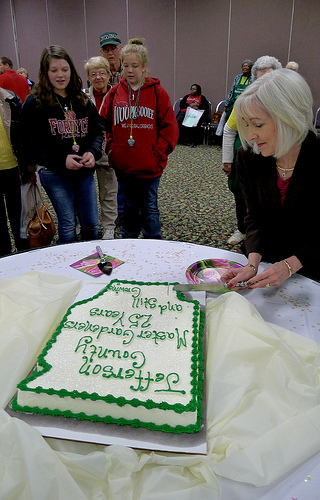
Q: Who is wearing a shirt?
A: The girl is wearing a shirt.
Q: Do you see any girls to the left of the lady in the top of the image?
A: Yes, there is a girl to the left of the lady.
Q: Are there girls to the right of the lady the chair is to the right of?
A: No, the girl is to the left of the lady.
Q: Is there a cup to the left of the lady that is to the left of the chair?
A: No, there is a girl to the left of the lady.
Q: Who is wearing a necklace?
A: The girl is wearing a necklace.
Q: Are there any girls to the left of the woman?
A: Yes, there is a girl to the left of the woman.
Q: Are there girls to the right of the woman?
A: No, the girl is to the left of the woman.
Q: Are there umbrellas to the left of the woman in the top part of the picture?
A: No, there is a girl to the left of the woman.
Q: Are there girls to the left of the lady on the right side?
A: Yes, there is a girl to the left of the lady.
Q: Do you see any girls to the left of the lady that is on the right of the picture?
A: Yes, there is a girl to the left of the lady.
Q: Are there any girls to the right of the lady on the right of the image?
A: No, the girl is to the left of the lady.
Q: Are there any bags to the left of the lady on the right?
A: No, there is a girl to the left of the lady.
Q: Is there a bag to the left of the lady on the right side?
A: No, there is a girl to the left of the lady.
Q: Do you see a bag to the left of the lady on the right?
A: No, there is a girl to the left of the lady.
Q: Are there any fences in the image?
A: No, there are no fences.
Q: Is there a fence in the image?
A: No, there are no fences.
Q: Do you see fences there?
A: No, there are no fences.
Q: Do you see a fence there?
A: No, there are no fences.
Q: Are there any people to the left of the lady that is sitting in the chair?
A: Yes, there is a person to the left of the lady.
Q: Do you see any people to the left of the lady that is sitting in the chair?
A: Yes, there is a person to the left of the lady.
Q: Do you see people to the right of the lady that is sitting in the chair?
A: No, the person is to the left of the lady.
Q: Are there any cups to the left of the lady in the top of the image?
A: No, there is a person to the left of the lady.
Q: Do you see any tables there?
A: Yes, there is a table.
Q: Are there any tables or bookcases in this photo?
A: Yes, there is a table.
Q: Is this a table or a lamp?
A: This is a table.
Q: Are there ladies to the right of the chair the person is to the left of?
A: Yes, there is a lady to the right of the chair.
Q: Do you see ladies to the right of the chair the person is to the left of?
A: Yes, there is a lady to the right of the chair.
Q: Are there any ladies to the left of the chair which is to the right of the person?
A: No, the lady is to the right of the chair.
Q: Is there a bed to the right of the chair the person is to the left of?
A: No, there is a lady to the right of the chair.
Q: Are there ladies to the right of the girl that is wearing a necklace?
A: Yes, there is a lady to the right of the girl.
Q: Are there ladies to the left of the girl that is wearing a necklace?
A: No, the lady is to the right of the girl.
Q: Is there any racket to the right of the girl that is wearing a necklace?
A: No, there is a lady to the right of the girl.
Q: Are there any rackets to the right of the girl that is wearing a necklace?
A: No, there is a lady to the right of the girl.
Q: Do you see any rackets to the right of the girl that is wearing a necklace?
A: No, there is a lady to the right of the girl.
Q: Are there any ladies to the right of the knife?
A: Yes, there is a lady to the right of the knife.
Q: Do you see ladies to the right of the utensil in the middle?
A: Yes, there is a lady to the right of the knife.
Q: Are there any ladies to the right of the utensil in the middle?
A: Yes, there is a lady to the right of the knife.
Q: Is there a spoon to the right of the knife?
A: No, there is a lady to the right of the knife.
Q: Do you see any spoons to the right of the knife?
A: No, there is a lady to the right of the knife.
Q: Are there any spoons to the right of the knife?
A: No, there is a lady to the right of the knife.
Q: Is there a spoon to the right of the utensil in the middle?
A: No, there is a lady to the right of the knife.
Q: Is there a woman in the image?
A: Yes, there is a woman.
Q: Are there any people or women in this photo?
A: Yes, there is a woman.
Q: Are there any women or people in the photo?
A: Yes, there is a woman.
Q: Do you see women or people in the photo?
A: Yes, there is a woman.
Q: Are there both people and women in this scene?
A: Yes, there are both a woman and a person.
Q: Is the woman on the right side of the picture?
A: Yes, the woman is on the right of the image.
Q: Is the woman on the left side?
A: No, the woman is on the right of the image.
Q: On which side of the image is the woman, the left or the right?
A: The woman is on the right of the image.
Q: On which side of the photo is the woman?
A: The woman is on the right of the image.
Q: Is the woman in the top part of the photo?
A: Yes, the woman is in the top of the image.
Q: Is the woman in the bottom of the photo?
A: No, the woman is in the top of the image.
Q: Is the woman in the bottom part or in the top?
A: The woman is in the top of the image.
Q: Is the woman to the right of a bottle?
A: No, the woman is to the right of a chair.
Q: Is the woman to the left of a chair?
A: No, the woman is to the right of a chair.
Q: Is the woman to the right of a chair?
A: Yes, the woman is to the right of a chair.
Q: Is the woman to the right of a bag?
A: No, the woman is to the right of a chair.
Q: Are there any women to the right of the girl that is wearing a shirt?
A: Yes, there is a woman to the right of the girl.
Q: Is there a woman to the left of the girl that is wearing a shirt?
A: No, the woman is to the right of the girl.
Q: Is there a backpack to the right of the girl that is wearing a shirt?
A: No, there is a woman to the right of the girl.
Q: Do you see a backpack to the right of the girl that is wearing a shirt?
A: No, there is a woman to the right of the girl.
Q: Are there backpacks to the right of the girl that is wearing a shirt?
A: No, there is a woman to the right of the girl.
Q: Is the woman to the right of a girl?
A: Yes, the woman is to the right of a girl.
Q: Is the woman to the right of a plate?
A: No, the woman is to the right of a girl.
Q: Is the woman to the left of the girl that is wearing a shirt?
A: No, the woman is to the right of the girl.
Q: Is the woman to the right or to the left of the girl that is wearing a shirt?
A: The woman is to the right of the girl.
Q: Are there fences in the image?
A: No, there are no fences.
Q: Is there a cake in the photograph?
A: Yes, there is a cake.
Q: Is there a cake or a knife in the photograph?
A: Yes, there is a cake.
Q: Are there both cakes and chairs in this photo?
A: Yes, there are both a cake and a chair.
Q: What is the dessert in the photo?
A: The dessert is a cake.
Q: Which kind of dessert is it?
A: The dessert is a cake.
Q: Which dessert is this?
A: That is a cake.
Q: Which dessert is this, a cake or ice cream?
A: That is a cake.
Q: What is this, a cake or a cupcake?
A: This is a cake.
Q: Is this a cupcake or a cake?
A: This is a cake.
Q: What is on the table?
A: The cake is on the table.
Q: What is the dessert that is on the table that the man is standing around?
A: The dessert is a cake.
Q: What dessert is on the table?
A: The dessert is a cake.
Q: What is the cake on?
A: The cake is on the table.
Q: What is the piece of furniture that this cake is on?
A: The piece of furniture is a table.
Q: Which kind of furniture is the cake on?
A: The cake is on the table.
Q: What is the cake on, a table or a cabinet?
A: The cake is on a table.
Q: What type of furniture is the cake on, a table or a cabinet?
A: The cake is on a table.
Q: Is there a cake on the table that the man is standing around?
A: Yes, there is a cake on the table.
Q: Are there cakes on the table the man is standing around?
A: Yes, there is a cake on the table.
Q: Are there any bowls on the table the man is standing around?
A: No, there is a cake on the table.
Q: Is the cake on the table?
A: Yes, the cake is on the table.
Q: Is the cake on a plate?
A: No, the cake is on the table.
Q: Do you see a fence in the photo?
A: No, there are no fences.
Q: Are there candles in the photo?
A: No, there are no candles.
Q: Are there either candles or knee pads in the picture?
A: No, there are no candles or knee pads.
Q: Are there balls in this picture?
A: No, there are no balls.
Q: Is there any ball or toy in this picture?
A: No, there are no balls or toys.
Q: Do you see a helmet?
A: No, there are no helmets.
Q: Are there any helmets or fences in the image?
A: No, there are no helmets or fences.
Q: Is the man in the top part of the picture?
A: Yes, the man is in the top of the image.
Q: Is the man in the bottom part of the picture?
A: No, the man is in the top of the image.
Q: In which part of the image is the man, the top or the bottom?
A: The man is in the top of the image.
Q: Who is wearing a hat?
A: The man is wearing a hat.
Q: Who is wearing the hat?
A: The man is wearing a hat.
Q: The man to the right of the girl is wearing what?
A: The man is wearing a hat.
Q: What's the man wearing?
A: The man is wearing a hat.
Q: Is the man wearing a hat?
A: Yes, the man is wearing a hat.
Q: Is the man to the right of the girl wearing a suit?
A: No, the man is wearing a hat.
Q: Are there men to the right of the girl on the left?
A: Yes, there is a man to the right of the girl.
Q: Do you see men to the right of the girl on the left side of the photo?
A: Yes, there is a man to the right of the girl.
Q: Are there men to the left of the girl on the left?
A: No, the man is to the right of the girl.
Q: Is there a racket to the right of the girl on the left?
A: No, there is a man to the right of the girl.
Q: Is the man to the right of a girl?
A: Yes, the man is to the right of a girl.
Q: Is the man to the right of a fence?
A: No, the man is to the right of a girl.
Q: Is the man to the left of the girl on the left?
A: No, the man is to the right of the girl.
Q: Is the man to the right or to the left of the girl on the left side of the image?
A: The man is to the right of the girl.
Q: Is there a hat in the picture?
A: Yes, there is a hat.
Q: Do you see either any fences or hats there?
A: Yes, there is a hat.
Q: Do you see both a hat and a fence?
A: No, there is a hat but no fences.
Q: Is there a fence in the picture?
A: No, there are no fences.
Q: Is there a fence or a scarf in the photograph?
A: No, there are no fences or scarves.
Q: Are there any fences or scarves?
A: No, there are no fences or scarves.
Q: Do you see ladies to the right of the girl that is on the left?
A: Yes, there is a lady to the right of the girl.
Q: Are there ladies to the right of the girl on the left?
A: Yes, there is a lady to the right of the girl.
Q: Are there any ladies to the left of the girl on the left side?
A: No, the lady is to the right of the girl.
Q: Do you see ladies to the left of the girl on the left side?
A: No, the lady is to the right of the girl.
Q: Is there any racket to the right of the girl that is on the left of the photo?
A: No, there is a lady to the right of the girl.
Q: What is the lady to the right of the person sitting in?
A: The lady is sitting in the chair.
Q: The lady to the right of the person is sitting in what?
A: The lady is sitting in the chair.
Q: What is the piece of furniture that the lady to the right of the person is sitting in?
A: The piece of furniture is a chair.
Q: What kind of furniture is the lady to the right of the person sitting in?
A: The lady is sitting in the chair.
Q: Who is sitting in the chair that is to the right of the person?
A: The lady is sitting in the chair.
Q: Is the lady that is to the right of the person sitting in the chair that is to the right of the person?
A: Yes, the lady is sitting in the chair.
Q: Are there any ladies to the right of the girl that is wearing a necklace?
A: Yes, there is a lady to the right of the girl.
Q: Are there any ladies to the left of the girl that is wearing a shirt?
A: No, the lady is to the right of the girl.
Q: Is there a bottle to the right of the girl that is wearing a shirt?
A: No, there is a lady to the right of the girl.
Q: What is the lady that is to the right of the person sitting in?
A: The lady is sitting in the chair.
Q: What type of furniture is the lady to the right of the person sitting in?
A: The lady is sitting in the chair.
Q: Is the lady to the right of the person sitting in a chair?
A: Yes, the lady is sitting in a chair.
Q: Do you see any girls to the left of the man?
A: Yes, there is a girl to the left of the man.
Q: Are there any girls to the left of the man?
A: Yes, there is a girl to the left of the man.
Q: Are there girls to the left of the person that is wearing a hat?
A: Yes, there is a girl to the left of the man.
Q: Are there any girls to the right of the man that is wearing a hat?
A: No, the girl is to the left of the man.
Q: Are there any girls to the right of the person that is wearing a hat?
A: No, the girl is to the left of the man.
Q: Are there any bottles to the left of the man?
A: No, there is a girl to the left of the man.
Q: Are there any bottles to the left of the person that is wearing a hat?
A: No, there is a girl to the left of the man.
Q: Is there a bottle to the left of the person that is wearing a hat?
A: No, there is a girl to the left of the man.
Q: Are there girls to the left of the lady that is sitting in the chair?
A: Yes, there is a girl to the left of the lady.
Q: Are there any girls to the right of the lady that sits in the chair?
A: No, the girl is to the left of the lady.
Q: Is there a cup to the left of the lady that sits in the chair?
A: No, there is a girl to the left of the lady.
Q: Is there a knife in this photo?
A: Yes, there is a knife.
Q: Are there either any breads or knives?
A: Yes, there is a knife.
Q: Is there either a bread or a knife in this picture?
A: Yes, there is a knife.